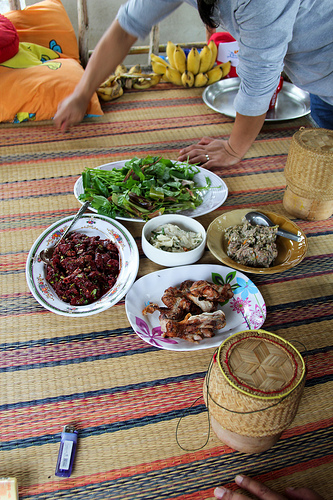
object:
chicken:
[162, 306, 226, 340]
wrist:
[224, 133, 242, 158]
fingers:
[195, 156, 213, 170]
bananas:
[185, 46, 202, 74]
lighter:
[53, 422, 80, 480]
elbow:
[256, 61, 284, 96]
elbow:
[113, 2, 153, 44]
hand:
[174, 134, 236, 173]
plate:
[72, 157, 229, 223]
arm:
[222, 0, 300, 161]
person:
[50, 1, 332, 173]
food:
[78, 155, 210, 221]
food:
[220, 224, 283, 267]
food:
[147, 220, 201, 252]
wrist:
[72, 82, 95, 103]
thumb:
[60, 115, 78, 133]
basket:
[201, 326, 306, 457]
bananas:
[219, 58, 233, 80]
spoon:
[38, 199, 92, 264]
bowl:
[140, 212, 208, 267]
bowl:
[205, 206, 307, 277]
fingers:
[182, 152, 208, 165]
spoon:
[244, 209, 300, 243]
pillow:
[0, 0, 106, 125]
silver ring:
[205, 152, 210, 161]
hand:
[50, 91, 90, 136]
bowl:
[124, 261, 265, 353]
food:
[44, 229, 119, 304]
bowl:
[24, 211, 138, 318]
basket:
[281, 124, 333, 221]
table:
[0, 66, 332, 498]